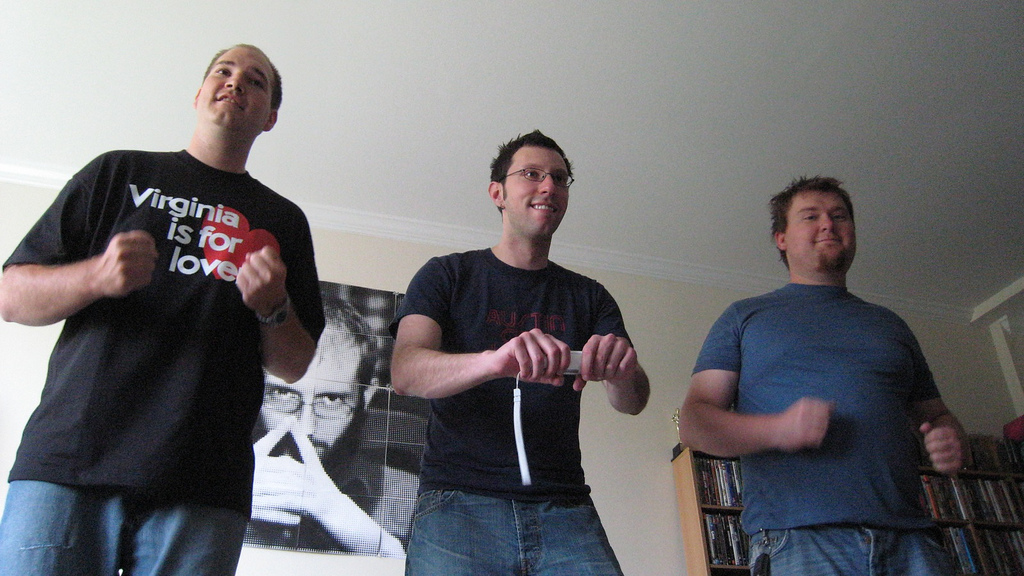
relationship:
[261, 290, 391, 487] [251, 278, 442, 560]
face on poster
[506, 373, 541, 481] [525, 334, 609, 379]
strap on wii remote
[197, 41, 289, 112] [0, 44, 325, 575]
hair on men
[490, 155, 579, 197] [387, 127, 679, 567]
glasses on man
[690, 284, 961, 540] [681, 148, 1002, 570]
shirt on man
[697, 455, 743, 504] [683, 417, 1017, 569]
dvd's on bookcase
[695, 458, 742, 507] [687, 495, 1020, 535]
dvd's on shelf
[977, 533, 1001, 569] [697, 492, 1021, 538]
movie on shelf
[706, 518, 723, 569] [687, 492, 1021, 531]
movie on shelf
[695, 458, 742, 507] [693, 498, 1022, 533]
dvd's on shelf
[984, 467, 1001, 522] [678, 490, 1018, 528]
movie on shelf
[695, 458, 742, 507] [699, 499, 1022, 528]
dvd's on shelf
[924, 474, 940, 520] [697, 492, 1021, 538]
movie on shelf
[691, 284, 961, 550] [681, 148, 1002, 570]
shirt on man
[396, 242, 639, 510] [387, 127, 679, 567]
shirt on man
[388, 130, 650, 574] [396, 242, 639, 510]
man in shirt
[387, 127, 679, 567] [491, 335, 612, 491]
man holding remote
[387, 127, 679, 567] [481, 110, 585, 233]
man in dark hair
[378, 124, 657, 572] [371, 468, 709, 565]
man wearing blue jeans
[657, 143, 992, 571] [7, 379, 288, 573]
man wearing blue jeans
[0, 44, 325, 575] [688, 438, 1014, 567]
men wearing blue jeans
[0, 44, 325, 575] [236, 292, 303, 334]
men wearing watch